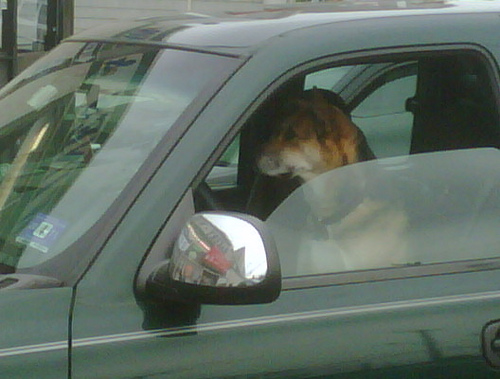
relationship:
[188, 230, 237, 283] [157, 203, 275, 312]
reflection on mirror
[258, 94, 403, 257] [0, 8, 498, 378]
dog in car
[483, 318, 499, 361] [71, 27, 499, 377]
handle of door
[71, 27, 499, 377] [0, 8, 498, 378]
door of car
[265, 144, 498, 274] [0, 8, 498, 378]
window of car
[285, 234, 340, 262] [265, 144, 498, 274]
reflection on window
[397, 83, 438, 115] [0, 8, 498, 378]
seat buckle in car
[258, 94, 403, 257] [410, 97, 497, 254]
dog in seat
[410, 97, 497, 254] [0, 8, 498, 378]
seat of car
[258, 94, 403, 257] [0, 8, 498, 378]
dog inside car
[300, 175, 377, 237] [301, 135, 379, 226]
collar around neck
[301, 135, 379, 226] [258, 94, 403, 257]
neck of dog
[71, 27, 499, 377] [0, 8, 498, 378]
door on car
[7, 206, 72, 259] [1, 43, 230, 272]
sticker on windshield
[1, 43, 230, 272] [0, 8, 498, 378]
windshield of car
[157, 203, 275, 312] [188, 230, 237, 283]
mirror with reflection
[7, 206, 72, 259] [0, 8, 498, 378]
sticker on car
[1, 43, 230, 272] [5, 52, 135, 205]
windshield with reflections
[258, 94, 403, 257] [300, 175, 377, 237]
dog with collar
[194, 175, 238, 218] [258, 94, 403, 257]
steering wheel in front of dog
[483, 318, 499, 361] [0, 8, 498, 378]
handle to car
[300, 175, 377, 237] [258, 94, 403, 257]
collar belonging dog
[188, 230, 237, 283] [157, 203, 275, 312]
reflection in mirror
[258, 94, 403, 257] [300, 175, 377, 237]
dog has collar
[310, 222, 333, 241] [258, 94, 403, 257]
tags for dog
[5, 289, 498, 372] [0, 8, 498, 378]
stripe on car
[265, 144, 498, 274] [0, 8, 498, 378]
window in car